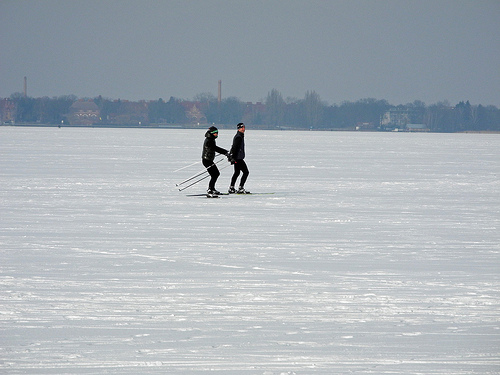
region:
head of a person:
[199, 119, 231, 137]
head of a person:
[232, 123, 254, 133]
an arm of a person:
[206, 138, 230, 155]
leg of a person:
[205, 163, 235, 183]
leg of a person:
[227, 168, 242, 183]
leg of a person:
[239, 165, 257, 183]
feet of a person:
[206, 191, 226, 199]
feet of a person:
[226, 175, 241, 197]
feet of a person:
[237, 185, 258, 197]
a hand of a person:
[220, 146, 238, 160]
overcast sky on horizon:
[1, 1, 497, 96]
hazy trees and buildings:
[4, 92, 497, 128]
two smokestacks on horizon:
[21, 76, 221, 100]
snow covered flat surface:
[3, 131, 498, 370]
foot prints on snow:
[129, 324, 454, 345]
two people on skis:
[173, 122, 268, 199]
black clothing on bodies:
[202, 132, 248, 192]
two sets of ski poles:
[175, 151, 234, 192]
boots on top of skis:
[188, 187, 275, 201]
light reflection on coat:
[202, 144, 212, 161]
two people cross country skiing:
[141, 94, 308, 205]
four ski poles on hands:
[172, 149, 229, 211]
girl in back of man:
[190, 124, 229, 218]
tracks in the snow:
[61, 221, 496, 348]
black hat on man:
[232, 112, 247, 134]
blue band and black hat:
[203, 117, 229, 145]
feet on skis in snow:
[200, 184, 258, 201]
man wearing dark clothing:
[228, 133, 244, 186]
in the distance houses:
[3, 99, 496, 124]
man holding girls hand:
[196, 145, 243, 197]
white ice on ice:
[318, 307, 350, 339]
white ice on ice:
[389, 170, 416, 202]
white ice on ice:
[27, 300, 53, 340]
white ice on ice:
[18, 261, 33, 294]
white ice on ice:
[80, 271, 105, 302]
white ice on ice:
[76, 235, 104, 260]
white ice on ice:
[75, 190, 125, 236]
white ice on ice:
[135, 298, 165, 326]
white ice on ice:
[208, 281, 246, 322]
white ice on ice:
[351, 296, 391, 330]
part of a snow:
[423, 213, 432, 225]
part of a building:
[358, 107, 366, 122]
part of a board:
[259, 193, 266, 217]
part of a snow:
[359, 232, 367, 295]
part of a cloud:
[313, 82, 320, 97]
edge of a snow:
[363, 263, 373, 293]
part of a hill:
[254, 203, 264, 232]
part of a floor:
[338, 148, 350, 193]